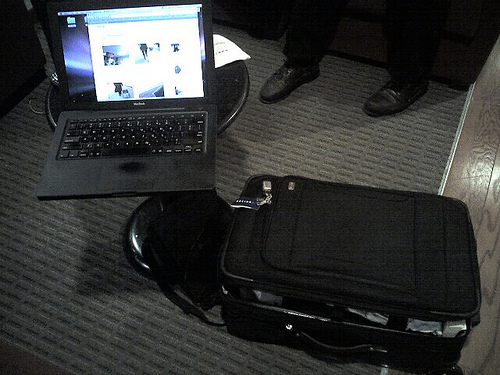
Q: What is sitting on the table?
A: Laptop.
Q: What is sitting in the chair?
A: Suitcase.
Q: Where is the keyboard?
A: Laptop.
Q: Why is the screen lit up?
A: Laptop is on.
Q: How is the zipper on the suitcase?
A: Open.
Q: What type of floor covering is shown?
A: Carpet.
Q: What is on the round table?
A: A laptop.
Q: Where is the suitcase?
A: On the floor.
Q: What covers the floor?
A: Gray carpet.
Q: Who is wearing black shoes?
A: The person in the room.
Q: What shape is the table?
A: Round.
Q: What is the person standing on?
A: Gray carpet.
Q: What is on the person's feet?
A: Black shoes.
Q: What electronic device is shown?
A: A laptop.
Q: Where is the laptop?
A: On a desk.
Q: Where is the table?
A: On the floor.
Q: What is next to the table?
A: A suitcase.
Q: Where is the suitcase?
A: On the floor.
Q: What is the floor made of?
A: Carpet.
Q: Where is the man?
A: Next to the table.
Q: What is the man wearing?
A: Dress pants.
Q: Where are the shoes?
A: On the man.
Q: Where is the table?
A: Under the laptop.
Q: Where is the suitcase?
A: On the ground.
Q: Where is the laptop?
A: On the table.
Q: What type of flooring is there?
A: Grey carpet.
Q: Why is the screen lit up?
A: The computer is on.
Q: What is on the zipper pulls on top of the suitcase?
A: Lock.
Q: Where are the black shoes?
A: By the chair.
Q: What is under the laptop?
A: Black table.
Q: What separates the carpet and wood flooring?
A: Metal strip.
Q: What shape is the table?
A: Circle.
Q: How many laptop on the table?
A: One.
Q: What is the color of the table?
A: Black.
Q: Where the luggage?
A: On the floor.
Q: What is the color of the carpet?
A: Gray.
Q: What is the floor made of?
A: A carpet.